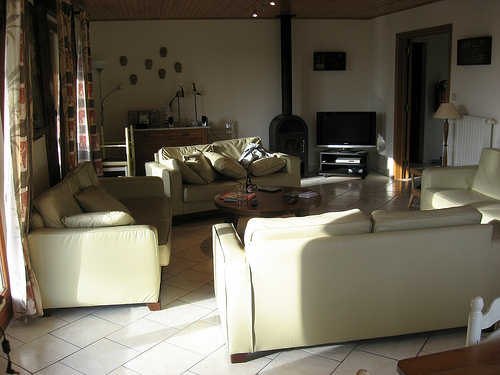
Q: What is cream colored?
A: Couch.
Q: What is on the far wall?
A: Wall decorations.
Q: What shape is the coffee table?
A: Round.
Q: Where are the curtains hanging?
A: On the window.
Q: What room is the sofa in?
A: Living room.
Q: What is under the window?
A: Sofa.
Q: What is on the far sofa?
A: Pillows.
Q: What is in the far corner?
A: Television.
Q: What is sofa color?
A: Cream.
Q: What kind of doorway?
A: Wood.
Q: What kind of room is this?
A: Living room.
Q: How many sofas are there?
A: 4.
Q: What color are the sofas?
A: Greenish.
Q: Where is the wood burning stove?
A: Against the far wall.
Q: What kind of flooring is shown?
A: Tile.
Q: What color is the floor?
A: White.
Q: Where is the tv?
A: In the corner.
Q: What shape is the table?
A: Round.